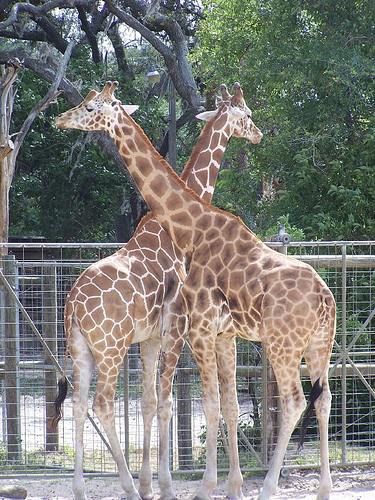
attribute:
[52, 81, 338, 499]
giraffe — brown, standing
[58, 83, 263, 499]
giraffe — brown, standing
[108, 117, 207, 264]
neck — crossed, long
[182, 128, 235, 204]
neck — long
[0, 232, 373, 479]
fence — metal, wire, wood, square-wired, silver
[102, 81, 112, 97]
horn — small, blunt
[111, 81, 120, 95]
horn — small, blunt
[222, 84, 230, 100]
horn — small, blunt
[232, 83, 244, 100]
horn — small, blunt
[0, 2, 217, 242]
tree — dry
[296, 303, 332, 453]
tail — black, dark, long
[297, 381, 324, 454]
hair — black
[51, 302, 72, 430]
tail — black, dark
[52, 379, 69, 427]
hair — black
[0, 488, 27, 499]
rock — large, smooth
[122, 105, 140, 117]
ear — pointy, large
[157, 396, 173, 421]
knee — knobbly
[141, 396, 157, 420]
knee — knobbly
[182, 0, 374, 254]
tree — green, tall, lush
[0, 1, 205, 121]
branches — intertwined, thick